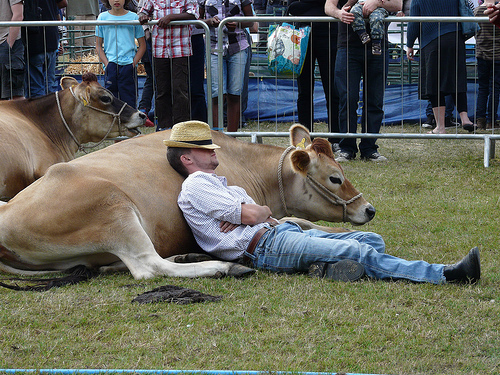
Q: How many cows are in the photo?
A: Two.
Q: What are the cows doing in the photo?
A: Laying down.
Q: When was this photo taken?
A: In the daytime.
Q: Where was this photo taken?
A: At a fair.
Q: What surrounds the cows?
A: A fence.